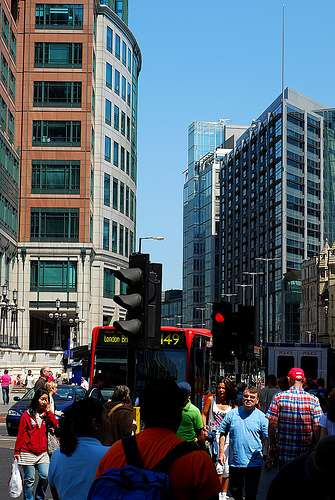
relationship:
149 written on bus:
[157, 329, 185, 352] [85, 322, 266, 424]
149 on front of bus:
[157, 329, 185, 352] [85, 322, 266, 424]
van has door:
[257, 338, 334, 396] [270, 346, 298, 386]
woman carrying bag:
[9, 385, 62, 500] [9, 458, 25, 500]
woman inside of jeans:
[9, 385, 62, 500] [22, 458, 54, 500]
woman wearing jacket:
[9, 385, 62, 500] [13, 409, 59, 459]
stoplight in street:
[210, 305, 229, 330] [3, 426, 64, 497]